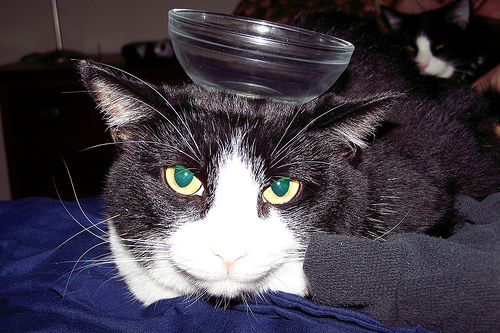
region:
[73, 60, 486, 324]
Cat with piercing eyes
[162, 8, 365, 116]
a clear bowl on top of cat's head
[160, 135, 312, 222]
green piercing eyes of cat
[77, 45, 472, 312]
black cat with white face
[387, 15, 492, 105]
black and white cat with yellow eyes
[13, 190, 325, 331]
a blue throw the cat is on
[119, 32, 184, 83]
a portable radio behind cat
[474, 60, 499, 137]
a hand petting the cat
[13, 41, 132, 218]
a brown cabinet against the wall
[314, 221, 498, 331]
part of a gray sleeve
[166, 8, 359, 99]
clear bowl on cat's head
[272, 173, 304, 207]
front cat's left eye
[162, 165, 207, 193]
the front cat's right eye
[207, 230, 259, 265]
The front cat's nose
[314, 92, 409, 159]
front cat's left ear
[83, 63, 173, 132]
front cat's right ear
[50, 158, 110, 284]
whiskers on cat's face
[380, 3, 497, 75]
black cat in the background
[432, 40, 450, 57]
back black cat's left eye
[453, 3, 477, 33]
back black cat's left ear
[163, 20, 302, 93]
Cat with a bowl on its head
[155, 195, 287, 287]
cat with a white face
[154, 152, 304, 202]
cat with green eyes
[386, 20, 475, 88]
cat with squinting eyes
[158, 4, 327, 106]
Glass bowl on a cat head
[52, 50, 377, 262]
Cat looking forward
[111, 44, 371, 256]
Cat laying on a bed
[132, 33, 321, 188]
Cat with a glass bowl on his head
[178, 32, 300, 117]
Glass bowl on cats head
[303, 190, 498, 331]
cats owners black sweat shirt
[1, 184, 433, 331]
navy blue blanket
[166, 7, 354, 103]
small, clear glass bowl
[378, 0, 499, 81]
black and white cat in the background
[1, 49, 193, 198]
wooden bedside table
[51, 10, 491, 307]
black and white cat with a bowl on its head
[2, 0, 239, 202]
grey painted bedroom wall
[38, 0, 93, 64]
silver base of a lamp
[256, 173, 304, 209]
cats yellow green eye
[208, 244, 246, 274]
cats light pink nose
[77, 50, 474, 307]
black and white cat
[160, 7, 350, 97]
glass bowl on cat's head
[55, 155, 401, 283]
white whiskers of cat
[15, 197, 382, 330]
blue blanket cat is laying on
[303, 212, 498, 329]
black shirt on bed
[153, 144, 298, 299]
white marking on cat's face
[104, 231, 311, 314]
white marking on cat's chest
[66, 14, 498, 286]
cat with bowl on his head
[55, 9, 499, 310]
two black and white cats